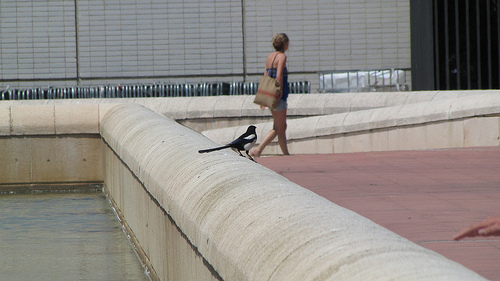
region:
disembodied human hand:
[436, 201, 497, 256]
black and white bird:
[195, 122, 260, 162]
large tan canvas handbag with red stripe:
[256, 72, 277, 108]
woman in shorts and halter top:
[252, 25, 292, 155]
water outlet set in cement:
[61, 140, 103, 177]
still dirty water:
[0, 182, 142, 277]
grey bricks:
[1, 4, 77, 74]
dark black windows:
[428, 3, 495, 87]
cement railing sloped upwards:
[324, 100, 498, 147]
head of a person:
[267, 26, 291, 57]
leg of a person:
[273, 116, 304, 154]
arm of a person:
[265, 51, 295, 89]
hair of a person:
[269, 28, 294, 46]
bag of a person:
[255, 36, 290, 120]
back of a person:
[262, 48, 289, 76]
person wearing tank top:
[240, 33, 315, 157]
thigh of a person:
[272, 106, 289, 128]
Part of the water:
[51, 196, 83, 240]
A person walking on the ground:
[248, 23, 294, 161]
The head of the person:
[270, 28, 291, 55]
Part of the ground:
[371, 160, 426, 201]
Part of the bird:
[240, 138, 247, 146]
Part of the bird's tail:
[198, 141, 214, 154]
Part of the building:
[124, 17, 198, 42]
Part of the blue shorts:
[276, 100, 285, 107]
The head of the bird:
[246, 121, 259, 133]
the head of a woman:
[256, 30, 293, 62]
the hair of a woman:
[265, 28, 302, 60]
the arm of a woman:
[261, 37, 316, 109]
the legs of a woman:
[256, 97, 308, 171]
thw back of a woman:
[251, 37, 307, 114]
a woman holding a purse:
[231, 17, 347, 117]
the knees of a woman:
[242, 108, 302, 160]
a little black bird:
[222, 100, 284, 160]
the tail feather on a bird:
[196, 125, 236, 161]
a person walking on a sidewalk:
[259, 32, 294, 157]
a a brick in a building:
[196, 124, 266, 159]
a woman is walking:
[233, 12, 308, 163]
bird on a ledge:
[197, 105, 294, 189]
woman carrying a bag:
[252, 60, 289, 117]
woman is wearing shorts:
[260, 94, 292, 119]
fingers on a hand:
[456, 217, 497, 245]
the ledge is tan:
[76, 99, 476, 277]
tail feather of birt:
[199, 137, 229, 170]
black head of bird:
[243, 120, 260, 133]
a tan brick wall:
[9, 5, 259, 70]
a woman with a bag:
[247, 24, 304, 161]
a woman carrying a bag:
[256, 31, 298, 153]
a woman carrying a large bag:
[249, 27, 301, 155]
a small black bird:
[196, 125, 260, 159]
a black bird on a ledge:
[196, 124, 261, 158]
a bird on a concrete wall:
[199, 123, 264, 160]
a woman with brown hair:
[255, 34, 302, 155]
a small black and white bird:
[200, 121, 260, 162]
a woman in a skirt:
[242, 27, 307, 155]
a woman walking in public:
[252, 21, 304, 153]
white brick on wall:
[78, 70, 90, 78]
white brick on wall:
[104, 70, 122, 78]